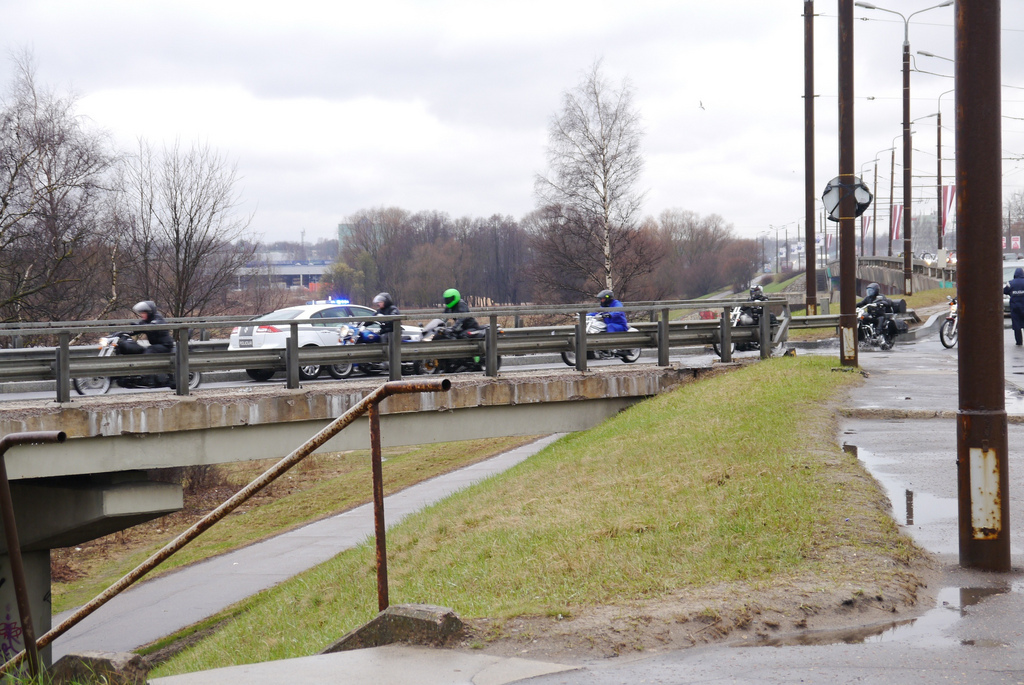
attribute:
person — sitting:
[134, 298, 179, 349]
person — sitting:
[355, 292, 398, 341]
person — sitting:
[440, 283, 476, 335]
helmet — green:
[443, 286, 457, 307]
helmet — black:
[593, 286, 616, 306]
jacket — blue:
[598, 291, 628, 323]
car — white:
[232, 291, 428, 377]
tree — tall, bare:
[536, 43, 653, 300]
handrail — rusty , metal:
[15, 370, 439, 674]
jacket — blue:
[595, 302, 640, 348]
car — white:
[220, 287, 439, 368]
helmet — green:
[437, 284, 463, 313]